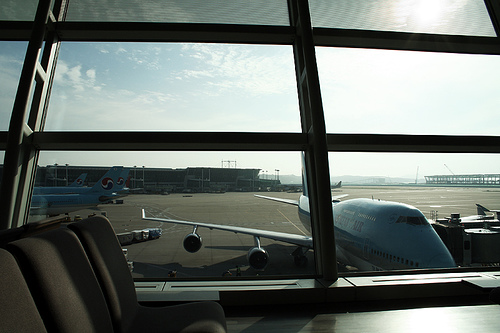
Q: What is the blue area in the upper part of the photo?
A: The sky.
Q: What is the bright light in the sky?
A: The sun.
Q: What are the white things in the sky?
A: Clouds.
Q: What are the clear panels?
A: Windows.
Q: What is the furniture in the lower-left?
A: Chairs.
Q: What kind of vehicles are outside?
A: Airplanes.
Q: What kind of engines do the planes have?
A: Jet engines.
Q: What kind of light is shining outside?
A: Sunlight.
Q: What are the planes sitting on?
A: The tarmac.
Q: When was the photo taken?
A: Afternoon.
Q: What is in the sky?
A: Clouds.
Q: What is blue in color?
A: The sky.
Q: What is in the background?
A: Building.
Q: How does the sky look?
A: Cloudy.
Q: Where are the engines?
A: Wing.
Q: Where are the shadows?
A: Chairs.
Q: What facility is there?
A: Airport.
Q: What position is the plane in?
A: Parked.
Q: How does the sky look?
A: Bright.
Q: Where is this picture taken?
A: An airport.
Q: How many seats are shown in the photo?
A: Three.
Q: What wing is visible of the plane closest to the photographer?
A: Right.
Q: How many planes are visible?
A: Four.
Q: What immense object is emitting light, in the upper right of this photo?
A: The Sun.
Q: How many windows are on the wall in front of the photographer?
A: Nine.